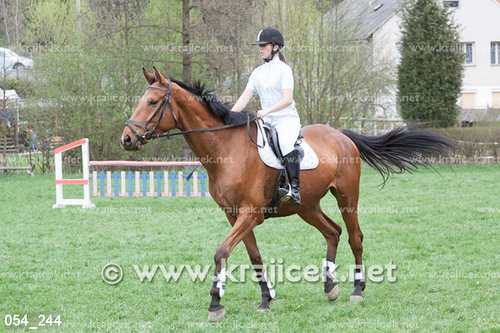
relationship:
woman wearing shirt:
[230, 24, 303, 209] [246, 57, 304, 122]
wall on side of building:
[440, 0, 498, 95] [284, 0, 493, 142]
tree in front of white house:
[390, 2, 465, 119] [427, 6, 494, 126]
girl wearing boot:
[229, 27, 300, 206] [276, 147, 303, 204]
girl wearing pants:
[229, 27, 300, 206] [269, 114, 302, 154]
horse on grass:
[113, 60, 455, 312] [3, 176, 497, 331]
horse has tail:
[113, 60, 455, 312] [340, 118, 458, 182]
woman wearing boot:
[230, 24, 303, 209] [276, 147, 303, 204]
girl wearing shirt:
[229, 27, 300, 206] [247, 57, 300, 115]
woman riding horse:
[230, 24, 303, 209] [113, 60, 455, 312]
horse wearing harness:
[113, 60, 455, 312] [125, 79, 262, 144]